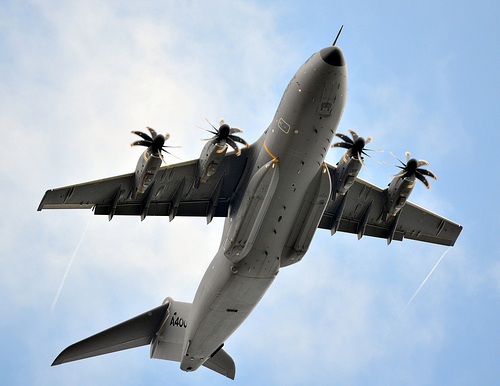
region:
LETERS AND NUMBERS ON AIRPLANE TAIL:
[166, 311, 186, 331]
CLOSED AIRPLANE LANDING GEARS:
[220, 152, 318, 272]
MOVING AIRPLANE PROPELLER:
[382, 146, 435, 187]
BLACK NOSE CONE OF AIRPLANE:
[315, 21, 350, 68]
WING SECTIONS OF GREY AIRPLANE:
[28, 152, 469, 250]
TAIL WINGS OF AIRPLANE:
[50, 290, 238, 376]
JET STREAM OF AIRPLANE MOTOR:
[43, 213, 103, 309]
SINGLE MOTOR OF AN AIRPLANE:
[130, 151, 166, 196]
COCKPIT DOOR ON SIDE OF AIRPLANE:
[273, 113, 293, 138]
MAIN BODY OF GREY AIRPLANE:
[241, 45, 345, 316]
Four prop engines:
[83, 33, 491, 266]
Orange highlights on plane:
[66, 15, 474, 265]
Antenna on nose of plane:
[316, 6, 371, 98]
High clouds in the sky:
[24, 3, 461, 384]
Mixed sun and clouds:
[15, 3, 498, 383]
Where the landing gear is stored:
[166, 114, 413, 307]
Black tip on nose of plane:
[292, 8, 382, 125]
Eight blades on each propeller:
[88, 80, 270, 205]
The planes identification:
[136, 289, 221, 353]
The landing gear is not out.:
[207, 117, 334, 342]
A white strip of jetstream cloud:
[411, 248, 459, 315]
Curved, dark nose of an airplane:
[321, 43, 349, 65]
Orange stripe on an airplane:
[261, 140, 278, 162]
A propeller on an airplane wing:
[129, 126, 181, 158]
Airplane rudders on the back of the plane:
[49, 293, 254, 383]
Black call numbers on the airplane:
[167, 304, 194, 330]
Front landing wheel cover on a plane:
[319, 91, 335, 123]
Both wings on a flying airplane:
[32, 151, 464, 243]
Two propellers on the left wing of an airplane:
[336, 126, 434, 207]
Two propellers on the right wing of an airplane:
[127, 113, 244, 185]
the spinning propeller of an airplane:
[378, 138, 444, 191]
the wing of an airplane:
[309, 152, 469, 259]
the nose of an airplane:
[277, 35, 364, 120]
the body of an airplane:
[178, 32, 352, 371]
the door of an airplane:
[273, 115, 293, 137]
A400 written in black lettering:
[165, 311, 198, 335]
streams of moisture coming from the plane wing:
[393, 228, 463, 326]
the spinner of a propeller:
[150, 134, 166, 147]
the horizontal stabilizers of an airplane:
[39, 282, 265, 380]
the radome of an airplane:
[314, 37, 354, 72]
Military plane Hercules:
[21, 0, 476, 379]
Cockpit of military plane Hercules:
[282, 40, 364, 114]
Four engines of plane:
[126, 107, 445, 212]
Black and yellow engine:
[377, 140, 439, 226]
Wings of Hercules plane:
[35, 143, 470, 255]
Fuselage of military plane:
[204, 68, 350, 384]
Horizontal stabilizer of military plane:
[45, 310, 247, 382]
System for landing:
[217, 150, 337, 275]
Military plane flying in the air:
[13, 15, 467, 385]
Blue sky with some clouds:
[7, 6, 489, 373]